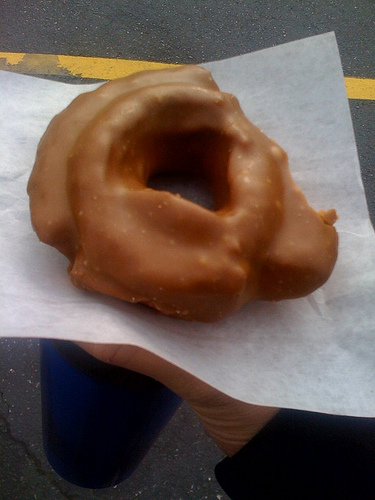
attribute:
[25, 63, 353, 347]
doughnut — bitten, glazed, frosted, brown, circular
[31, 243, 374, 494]
person — dressed, holding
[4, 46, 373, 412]
paper — white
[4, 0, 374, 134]
road — cracked, black, rocky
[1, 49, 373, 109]
line — yello, faded, yellow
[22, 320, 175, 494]
cup — black, plastic, blue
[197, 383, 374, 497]
sleeve — black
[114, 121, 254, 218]
hole — irregular